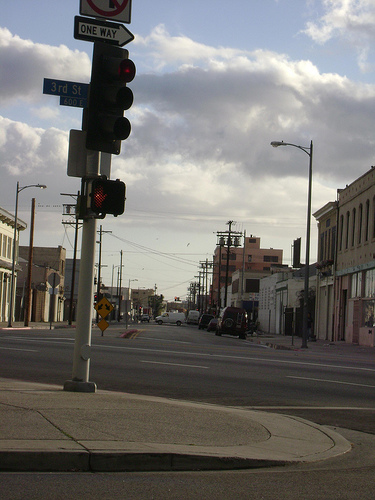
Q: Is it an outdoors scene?
A: Yes, it is outdoors.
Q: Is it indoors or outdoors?
A: It is outdoors.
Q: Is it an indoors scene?
A: No, it is outdoors.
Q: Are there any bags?
A: No, there are no bags.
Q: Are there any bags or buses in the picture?
A: No, there are no bags or buses.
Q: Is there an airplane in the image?
A: No, there are no airplanes.